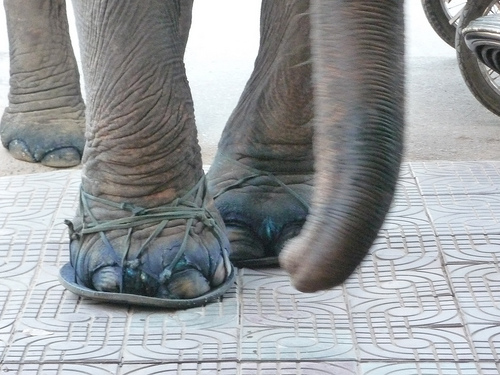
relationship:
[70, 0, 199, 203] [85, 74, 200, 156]
elephant's skin on knee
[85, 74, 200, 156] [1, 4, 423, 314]
knee on elephant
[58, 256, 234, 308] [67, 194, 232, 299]
shoe on foot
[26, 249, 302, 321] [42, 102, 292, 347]
shoe on elephant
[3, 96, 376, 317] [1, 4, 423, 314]
feet on elephant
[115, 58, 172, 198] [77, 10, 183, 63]
elephant's skin on leg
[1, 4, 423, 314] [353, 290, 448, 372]
elephant on sidewalk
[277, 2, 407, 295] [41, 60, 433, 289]
trunk of elephants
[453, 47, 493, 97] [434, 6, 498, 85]
wheel of bike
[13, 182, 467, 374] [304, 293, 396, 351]
designs on ground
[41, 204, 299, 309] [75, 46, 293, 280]
feet of elephant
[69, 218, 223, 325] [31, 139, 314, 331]
shoes with feet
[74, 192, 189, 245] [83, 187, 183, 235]
strings tie shoes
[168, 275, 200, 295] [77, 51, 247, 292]
nail on feet